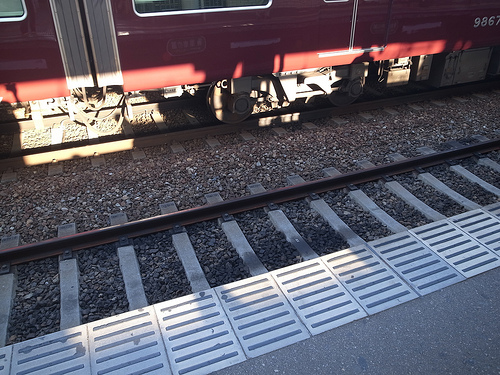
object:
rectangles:
[0, 201, 499, 374]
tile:
[7, 324, 90, 374]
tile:
[86, 304, 172, 374]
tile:
[152, 288, 249, 374]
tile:
[213, 271, 312, 359]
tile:
[270, 256, 370, 338]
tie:
[56, 219, 83, 330]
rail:
[0, 73, 495, 265]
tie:
[109, 208, 151, 311]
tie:
[158, 200, 213, 294]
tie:
[204, 190, 269, 277]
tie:
[246, 180, 319, 262]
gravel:
[1, 84, 499, 343]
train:
[0, 0, 500, 127]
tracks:
[0, 79, 500, 273]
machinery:
[206, 50, 500, 126]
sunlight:
[0, 40, 450, 173]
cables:
[68, 87, 136, 137]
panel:
[49, 1, 94, 96]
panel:
[79, 1, 126, 89]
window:
[133, 1, 271, 15]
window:
[0, 0, 25, 18]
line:
[346, 0, 367, 57]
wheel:
[205, 78, 259, 124]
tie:
[46, 118, 66, 177]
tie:
[86, 119, 106, 168]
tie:
[122, 120, 148, 162]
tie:
[149, 110, 188, 155]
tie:
[183, 107, 223, 150]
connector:
[51, 0, 124, 96]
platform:
[0, 202, 499, 374]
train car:
[81, 0, 500, 126]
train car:
[0, 1, 94, 106]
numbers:
[470, 16, 499, 28]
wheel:
[327, 81, 361, 107]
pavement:
[0, 206, 500, 373]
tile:
[321, 244, 421, 317]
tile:
[364, 230, 469, 298]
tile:
[407, 229, 499, 280]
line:
[0, 204, 499, 350]